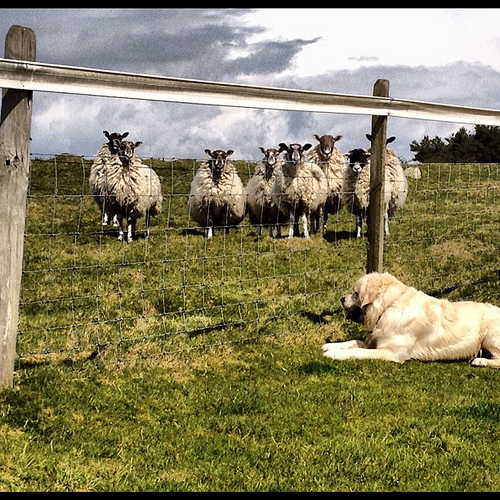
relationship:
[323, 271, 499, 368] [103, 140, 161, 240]
dog watching sheep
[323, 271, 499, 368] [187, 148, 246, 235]
dog watching sheep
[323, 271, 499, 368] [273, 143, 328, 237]
dog watching sheep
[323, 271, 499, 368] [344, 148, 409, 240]
dog watching sheep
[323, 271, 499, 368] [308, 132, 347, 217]
dog watching sheep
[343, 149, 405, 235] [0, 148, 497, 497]
sheep in field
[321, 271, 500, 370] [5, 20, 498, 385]
dog by fence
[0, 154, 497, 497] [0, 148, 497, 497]
grass on field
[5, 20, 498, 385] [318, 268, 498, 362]
fence in front of dog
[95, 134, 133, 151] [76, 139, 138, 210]
head on sheep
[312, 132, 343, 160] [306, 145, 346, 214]
head on sheep body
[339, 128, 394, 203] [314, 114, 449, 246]
head on sheep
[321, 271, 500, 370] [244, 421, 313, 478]
dog laying on grass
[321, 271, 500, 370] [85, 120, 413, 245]
dog watching sheeps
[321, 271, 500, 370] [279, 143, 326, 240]
dog guarding sheep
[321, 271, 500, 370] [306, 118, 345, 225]
dog guarding sheep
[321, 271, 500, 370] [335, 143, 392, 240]
dog guarding sheep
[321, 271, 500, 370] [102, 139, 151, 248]
dog guarding sheep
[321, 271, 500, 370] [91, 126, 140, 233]
dog guarding sheep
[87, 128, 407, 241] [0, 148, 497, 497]
sheep in field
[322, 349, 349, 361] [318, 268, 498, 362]
paw of dog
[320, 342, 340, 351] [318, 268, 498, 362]
paw of dog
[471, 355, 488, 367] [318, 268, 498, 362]
paw of dog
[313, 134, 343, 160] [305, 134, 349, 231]
head of sheep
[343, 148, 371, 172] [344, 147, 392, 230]
head of sheep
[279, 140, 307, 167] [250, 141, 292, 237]
head of sheep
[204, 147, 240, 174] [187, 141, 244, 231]
head of sheep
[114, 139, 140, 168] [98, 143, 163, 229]
head of sheep